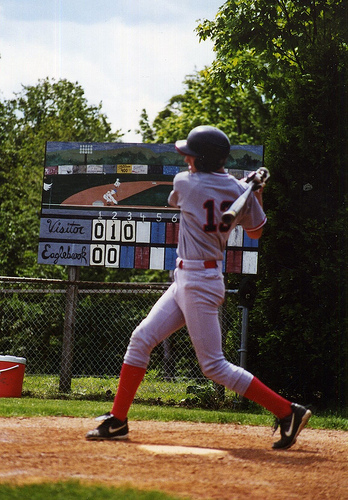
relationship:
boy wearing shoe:
[83, 125, 316, 452] [85, 411, 130, 442]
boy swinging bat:
[85, 125, 312, 452] [235, 167, 260, 214]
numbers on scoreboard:
[91, 220, 138, 269] [45, 140, 259, 275]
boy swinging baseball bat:
[85, 125, 312, 452] [223, 169, 257, 224]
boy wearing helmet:
[85, 125, 312, 452] [174, 125, 232, 173]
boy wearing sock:
[83, 125, 316, 452] [239, 372, 295, 421]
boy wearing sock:
[83, 125, 316, 452] [106, 358, 149, 422]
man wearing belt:
[85, 124, 312, 448] [174, 256, 224, 270]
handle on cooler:
[1, 361, 21, 378] [0, 353, 27, 397]